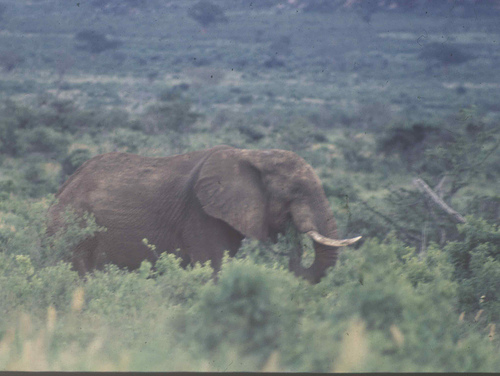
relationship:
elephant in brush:
[30, 136, 366, 287] [0, 0, 498, 375]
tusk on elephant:
[306, 230, 362, 247] [30, 136, 366, 287]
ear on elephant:
[195, 150, 267, 231] [92, 123, 329, 265]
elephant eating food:
[40, 144, 362, 285] [279, 217, 300, 245]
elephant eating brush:
[30, 136, 366, 287] [11, 185, 498, 374]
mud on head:
[251, 145, 301, 173] [252, 150, 322, 235]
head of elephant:
[252, 150, 322, 235] [54, 150, 359, 292]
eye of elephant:
[278, 194, 292, 208] [57, 141, 370, 281]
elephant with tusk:
[40, 144, 362, 285] [303, 227, 361, 246]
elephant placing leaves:
[30, 136, 366, 287] [268, 226, 314, 262]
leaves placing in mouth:
[268, 226, 314, 262] [273, 207, 302, 241]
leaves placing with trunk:
[268, 226, 314, 262] [285, 210, 340, 283]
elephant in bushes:
[40, 144, 362, 285] [108, 275, 243, 373]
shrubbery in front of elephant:
[181, 247, 357, 374] [30, 136, 366, 287]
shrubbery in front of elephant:
[359, 229, 493, 365] [30, 136, 366, 287]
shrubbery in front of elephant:
[82, 254, 152, 320] [30, 136, 366, 287]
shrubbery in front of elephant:
[5, 204, 86, 321] [30, 136, 366, 287]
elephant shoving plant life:
[40, 144, 362, 285] [275, 227, 305, 257]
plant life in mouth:
[275, 227, 305, 257] [277, 206, 307, 237]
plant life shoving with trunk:
[275, 227, 305, 257] [287, 189, 371, 286]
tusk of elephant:
[306, 230, 361, 245] [45, 143, 337, 283]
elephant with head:
[40, 144, 362, 285] [271, 150, 362, 272]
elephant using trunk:
[40, 144, 362, 285] [304, 221, 369, 251]